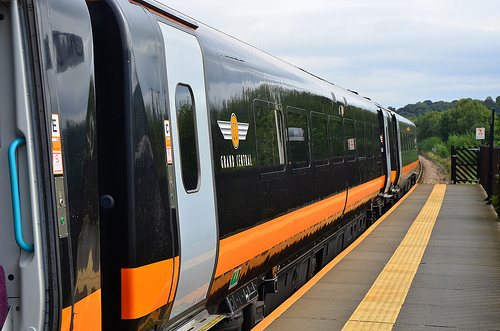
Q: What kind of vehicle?
A: Train.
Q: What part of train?
A: Door.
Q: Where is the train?
A: Tracks.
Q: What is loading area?
A: Concrete.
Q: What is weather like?
A: Slightly cloudy.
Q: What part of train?
A: Windows.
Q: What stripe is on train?
A: Orange.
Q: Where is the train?
A: Station.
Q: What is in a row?
A: Windows.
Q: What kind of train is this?
A: Passenger train.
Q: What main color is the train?
A: Black.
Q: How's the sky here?
A: Overcast.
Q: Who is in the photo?
A: Nobody.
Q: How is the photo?
A: Clear.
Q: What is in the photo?
A: A train.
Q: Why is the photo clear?
A: Its during the day.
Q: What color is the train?
A: Black.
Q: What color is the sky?
A: White and blue.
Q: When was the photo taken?
A: Daytime.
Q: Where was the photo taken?
A: Train tracks.